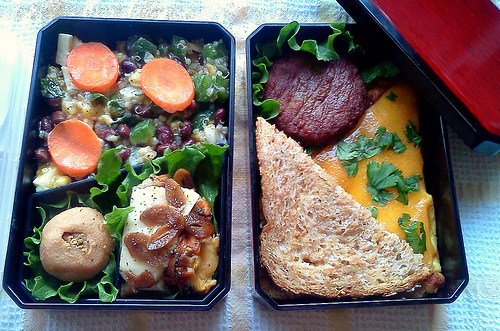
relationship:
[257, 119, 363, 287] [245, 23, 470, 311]
bread in container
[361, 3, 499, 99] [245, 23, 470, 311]
top of container resting on container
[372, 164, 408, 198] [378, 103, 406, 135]
parsley on top of cheese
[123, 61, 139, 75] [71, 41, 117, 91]
bean next to carrot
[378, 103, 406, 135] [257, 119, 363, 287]
cheese next to bread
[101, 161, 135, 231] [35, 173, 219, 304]
leaf of lettuce under food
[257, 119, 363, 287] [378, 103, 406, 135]
bread next to cheese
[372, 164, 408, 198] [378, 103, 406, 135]
parsley on cheese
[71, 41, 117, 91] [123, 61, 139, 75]
carrot next to bean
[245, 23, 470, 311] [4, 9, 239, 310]
container next to container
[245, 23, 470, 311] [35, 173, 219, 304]
container filled with food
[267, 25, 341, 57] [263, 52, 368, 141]
leaf of lettuce under meat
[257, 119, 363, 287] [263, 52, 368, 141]
bread next to meat